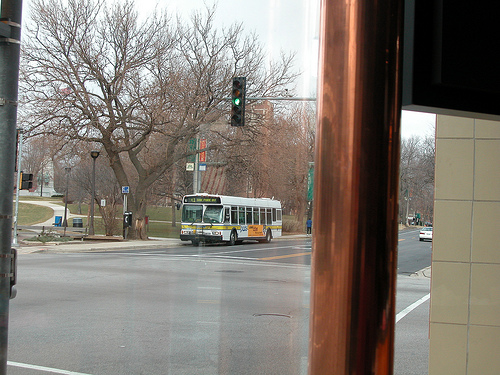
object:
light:
[18, 170, 34, 190]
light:
[210, 230, 221, 236]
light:
[180, 229, 192, 235]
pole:
[88, 160, 97, 235]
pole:
[192, 135, 200, 192]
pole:
[10, 130, 20, 247]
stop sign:
[229, 77, 246, 127]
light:
[232, 97, 243, 106]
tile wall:
[429, 114, 499, 374]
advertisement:
[239, 223, 268, 236]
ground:
[461, 126, 492, 174]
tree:
[223, 117, 315, 234]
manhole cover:
[251, 312, 293, 325]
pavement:
[8, 215, 433, 374]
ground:
[415, 171, 464, 231]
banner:
[197, 137, 208, 170]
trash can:
[55, 215, 63, 227]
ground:
[391, 201, 411, 237]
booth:
[121, 211, 133, 239]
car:
[417, 225, 433, 242]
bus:
[180, 193, 282, 246]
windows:
[223, 207, 231, 223]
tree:
[18, 0, 304, 238]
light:
[90, 151, 100, 159]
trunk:
[123, 194, 148, 240]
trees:
[398, 135, 436, 227]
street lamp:
[87, 150, 101, 234]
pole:
[122, 193, 127, 235]